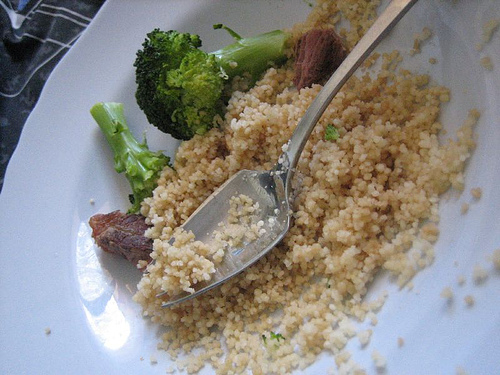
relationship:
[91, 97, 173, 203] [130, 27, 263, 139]
green stem of broccoli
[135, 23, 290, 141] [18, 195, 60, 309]
broccoli on plate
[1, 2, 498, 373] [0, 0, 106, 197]
plate on mat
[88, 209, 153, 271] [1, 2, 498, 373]
food on plate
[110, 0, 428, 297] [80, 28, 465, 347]
spoon holding food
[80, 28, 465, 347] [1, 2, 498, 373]
food on plate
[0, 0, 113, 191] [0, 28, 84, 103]
mat has stripe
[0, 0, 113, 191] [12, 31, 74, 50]
mat has stripe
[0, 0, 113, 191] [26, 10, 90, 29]
mat has stripe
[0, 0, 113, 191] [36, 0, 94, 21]
mat has stripe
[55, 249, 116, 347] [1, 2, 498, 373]
light on plate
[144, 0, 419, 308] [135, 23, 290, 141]
spoon in broccoli